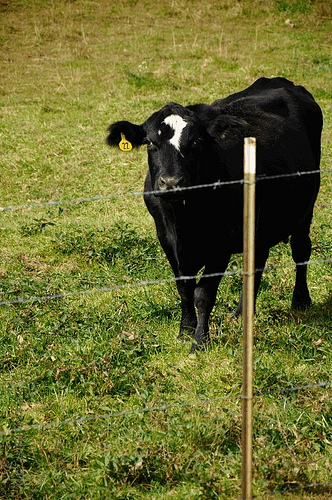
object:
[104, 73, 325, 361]
cow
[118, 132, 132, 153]
tag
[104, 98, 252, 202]
head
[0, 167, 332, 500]
fence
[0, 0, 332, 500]
field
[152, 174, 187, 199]
nose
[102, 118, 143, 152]
ear